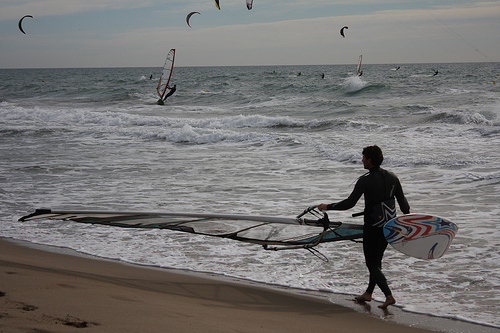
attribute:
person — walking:
[328, 154, 401, 308]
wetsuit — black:
[349, 143, 401, 299]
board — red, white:
[375, 210, 462, 267]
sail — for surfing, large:
[40, 207, 388, 260]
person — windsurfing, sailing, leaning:
[159, 84, 177, 104]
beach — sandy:
[6, 240, 356, 326]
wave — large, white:
[344, 67, 375, 106]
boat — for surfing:
[371, 198, 462, 277]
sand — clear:
[12, 240, 141, 268]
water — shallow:
[337, 298, 475, 331]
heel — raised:
[385, 294, 396, 308]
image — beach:
[6, 10, 499, 323]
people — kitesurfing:
[142, 51, 446, 113]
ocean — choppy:
[6, 67, 497, 322]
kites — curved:
[22, 9, 353, 49]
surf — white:
[71, 150, 323, 285]